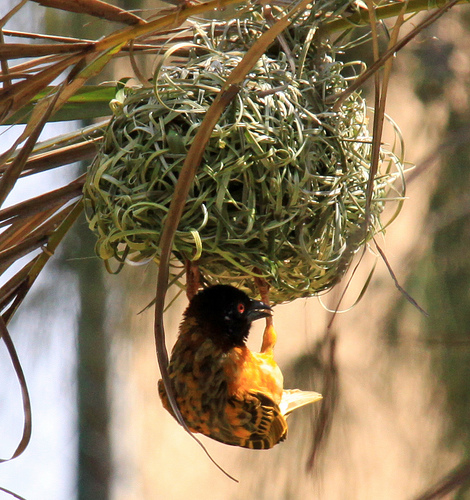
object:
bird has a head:
[151, 256, 332, 452]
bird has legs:
[245, 256, 284, 360]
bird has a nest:
[80, 8, 408, 466]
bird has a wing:
[220, 387, 292, 453]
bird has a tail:
[159, 257, 323, 453]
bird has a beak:
[154, 253, 327, 458]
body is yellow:
[160, 328, 287, 452]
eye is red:
[237, 303, 245, 311]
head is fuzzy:
[178, 281, 274, 350]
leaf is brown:
[154, 2, 313, 489]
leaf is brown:
[325, 7, 429, 329]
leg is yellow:
[248, 267, 283, 359]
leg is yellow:
[181, 251, 203, 302]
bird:
[155, 251, 323, 453]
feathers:
[177, 357, 225, 407]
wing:
[192, 382, 287, 451]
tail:
[279, 386, 325, 418]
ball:
[74, 0, 404, 308]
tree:
[2, 4, 469, 500]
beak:
[245, 296, 274, 323]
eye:
[233, 302, 244, 315]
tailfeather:
[281, 384, 326, 421]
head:
[181, 278, 274, 351]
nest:
[78, 8, 418, 311]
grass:
[88, 15, 419, 304]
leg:
[247, 258, 279, 352]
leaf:
[153, 0, 318, 486]